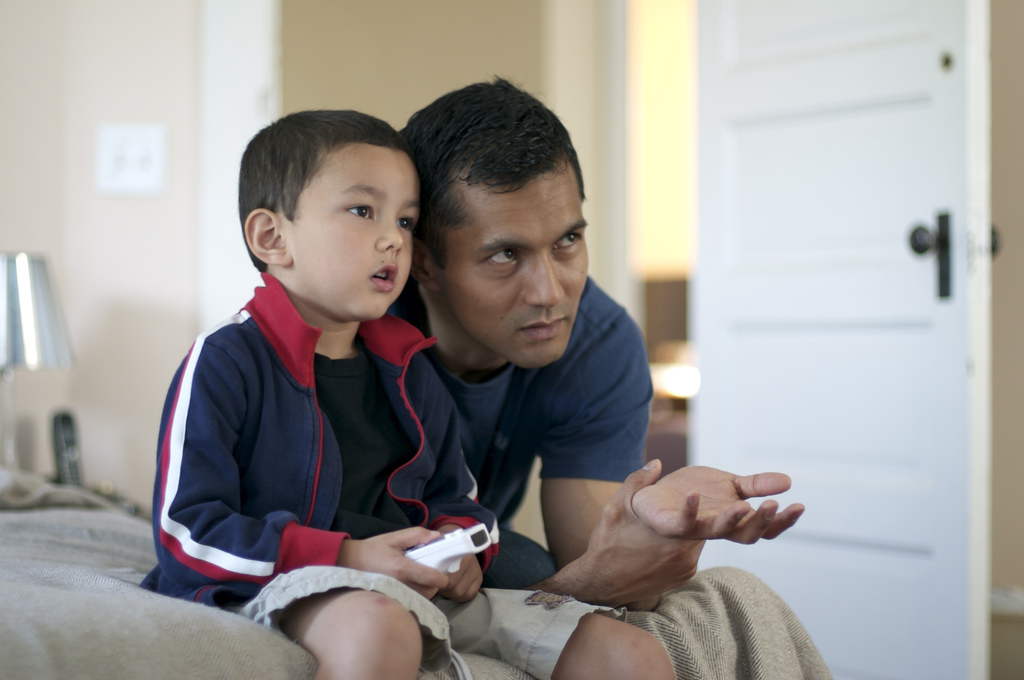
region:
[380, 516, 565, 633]
wii remote the boy is holding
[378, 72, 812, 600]
the dad next to the boy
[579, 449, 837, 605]
the hands of the dad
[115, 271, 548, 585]
the jacket on the boy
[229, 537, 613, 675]
the shorts on the boy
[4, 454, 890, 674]
the bed they are on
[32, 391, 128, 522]
the cordless phone on the table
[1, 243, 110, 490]
the lamp on the table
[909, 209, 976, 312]
the doorknob on the white door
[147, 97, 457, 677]
young boy with a red & black jacket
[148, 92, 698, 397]
Father and son together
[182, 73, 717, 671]
young boy with a man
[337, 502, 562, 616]
Wii remote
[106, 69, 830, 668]
two guys looking away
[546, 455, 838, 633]
a man's hands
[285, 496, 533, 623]
a boy's hands holding a Wii controller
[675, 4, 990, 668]
The white door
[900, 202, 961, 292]
The black door knob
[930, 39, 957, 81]
The black spot on the door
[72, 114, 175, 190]
The white light switch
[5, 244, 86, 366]
the steel lamp shade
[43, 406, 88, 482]
The black and gray cordless phone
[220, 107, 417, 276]
The hair on the young child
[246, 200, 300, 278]
The ear on the young child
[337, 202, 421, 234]
the eyes on the young child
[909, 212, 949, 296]
the door knob is black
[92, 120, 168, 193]
the light switch is white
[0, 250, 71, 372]
the lamp shade is silver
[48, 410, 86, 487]
the phone is black and grey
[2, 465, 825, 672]
the bed is beige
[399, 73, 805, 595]
the man has a blue shirt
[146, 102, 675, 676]
the boy is holding a controller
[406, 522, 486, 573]
the wii remote is white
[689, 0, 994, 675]
the door is white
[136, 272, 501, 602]
the shirt is red white and blue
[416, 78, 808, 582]
man in a shirt sleeve shirt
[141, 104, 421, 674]
boy in a blue, red, and white jacket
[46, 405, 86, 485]
a cordless house phone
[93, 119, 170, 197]
light switch fixture on the wall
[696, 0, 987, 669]
a white opened door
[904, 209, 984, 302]
doorknob on a white door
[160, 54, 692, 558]
The man and the boy are having a conversation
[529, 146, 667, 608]
a man weraing a shirt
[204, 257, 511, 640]
a boy wearing a jacket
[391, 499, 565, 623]
a white wii remote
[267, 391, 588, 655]
a boy holding a wii remote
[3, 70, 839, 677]
Man and a boy on the bed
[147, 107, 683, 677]
Boy holding white wii remote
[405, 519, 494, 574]
White wii remote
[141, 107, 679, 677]
Boy in brown shorts holding Wii remote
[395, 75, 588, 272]
black short hair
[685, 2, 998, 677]
white door with black door knob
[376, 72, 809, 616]
Man wearing blue shirt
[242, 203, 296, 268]
Ear of the boy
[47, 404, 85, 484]
Phone in the background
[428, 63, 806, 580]
a man on the bed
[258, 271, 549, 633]
a boy wearing a shirt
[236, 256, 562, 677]
a boy holding a wii remote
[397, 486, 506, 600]
a wii remote is white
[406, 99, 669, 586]
a man wearing a shirt